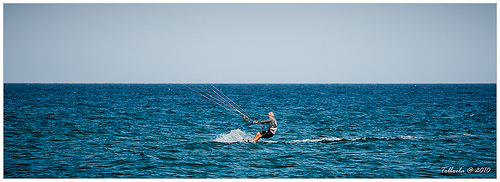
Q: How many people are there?
A: One.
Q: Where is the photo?
A: Ocean.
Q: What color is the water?
A: Blue.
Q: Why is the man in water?
A: Parasailing.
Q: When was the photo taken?
A: Morning.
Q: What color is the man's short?
A: Black.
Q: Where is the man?
A: Water.